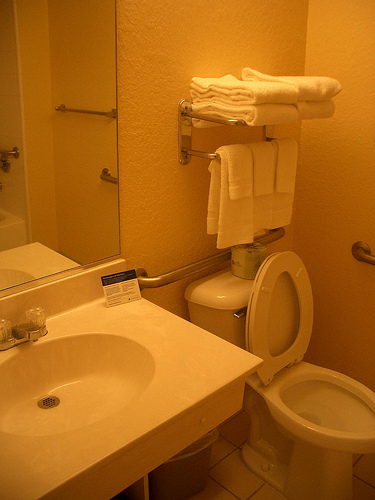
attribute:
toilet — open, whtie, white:
[181, 250, 373, 499]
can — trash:
[149, 434, 219, 495]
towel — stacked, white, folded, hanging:
[188, 73, 300, 111]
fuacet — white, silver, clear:
[0, 304, 52, 355]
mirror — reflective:
[2, 0, 123, 295]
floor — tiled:
[194, 409, 373, 497]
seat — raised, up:
[245, 247, 316, 384]